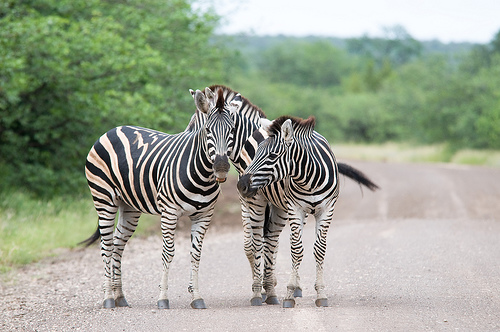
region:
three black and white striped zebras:
[69, 86, 382, 311]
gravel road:
[2, 155, 499, 330]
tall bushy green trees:
[3, 0, 224, 189]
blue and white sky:
[193, 1, 498, 43]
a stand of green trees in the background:
[241, 20, 497, 140]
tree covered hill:
[222, 30, 482, 65]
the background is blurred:
[200, 0, 495, 151]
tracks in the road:
[353, 155, 481, 288]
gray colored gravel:
[0, 218, 497, 328]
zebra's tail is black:
[335, 160, 381, 194]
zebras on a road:
[14, 28, 477, 288]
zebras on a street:
[44, 16, 499, 325]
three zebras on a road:
[57, 13, 442, 325]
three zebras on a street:
[40, 61, 420, 328]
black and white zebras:
[72, 58, 498, 328]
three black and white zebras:
[40, 36, 470, 327]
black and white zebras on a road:
[87, 68, 439, 329]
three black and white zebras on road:
[9, 72, 465, 329]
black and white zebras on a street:
[27, 50, 443, 321]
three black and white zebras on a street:
[28, 96, 411, 329]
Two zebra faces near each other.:
[193, 82, 285, 198]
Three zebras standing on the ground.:
[81, 85, 381, 312]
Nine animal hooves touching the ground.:
[102, 285, 329, 308]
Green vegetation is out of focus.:
[1, 1, 495, 188]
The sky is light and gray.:
[185, 0, 499, 44]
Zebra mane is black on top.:
[268, 112, 318, 132]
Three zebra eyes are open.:
[203, 125, 280, 159]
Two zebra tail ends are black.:
[76, 162, 379, 247]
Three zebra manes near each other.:
[205, 83, 317, 135]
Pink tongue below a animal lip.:
[210, 171, 230, 183]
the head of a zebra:
[185, 65, 306, 182]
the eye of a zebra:
[193, 120, 220, 143]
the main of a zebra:
[206, 80, 248, 117]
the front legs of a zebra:
[133, 202, 235, 319]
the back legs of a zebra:
[84, 178, 161, 312]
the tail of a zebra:
[320, 144, 400, 224]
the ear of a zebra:
[274, 113, 310, 143]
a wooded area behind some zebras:
[16, 0, 467, 128]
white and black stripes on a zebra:
[85, 86, 310, 237]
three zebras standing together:
[57, 45, 474, 307]